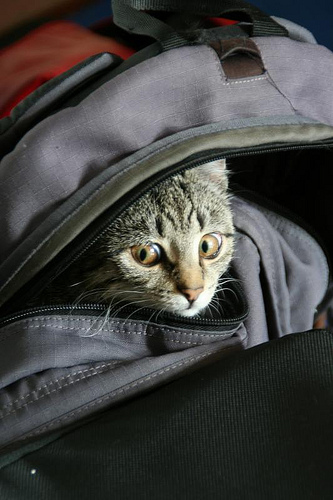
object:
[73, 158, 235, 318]
cat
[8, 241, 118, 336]
zipper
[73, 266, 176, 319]
whiskers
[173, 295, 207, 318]
mouth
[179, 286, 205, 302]
nose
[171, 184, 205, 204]
gray fur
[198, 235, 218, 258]
green eyes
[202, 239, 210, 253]
pupil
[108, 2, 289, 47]
strap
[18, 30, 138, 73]
patch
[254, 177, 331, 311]
lining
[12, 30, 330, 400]
backpack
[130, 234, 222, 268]
eyes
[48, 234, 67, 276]
right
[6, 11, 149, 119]
red bag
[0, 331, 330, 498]
black bag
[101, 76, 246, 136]
material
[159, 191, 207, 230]
stripes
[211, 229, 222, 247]
whites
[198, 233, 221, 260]
eye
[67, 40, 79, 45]
plastic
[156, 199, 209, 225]
head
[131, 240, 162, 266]
eye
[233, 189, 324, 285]
jacket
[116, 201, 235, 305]
face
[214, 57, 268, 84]
stitching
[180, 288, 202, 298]
pink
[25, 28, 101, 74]
red